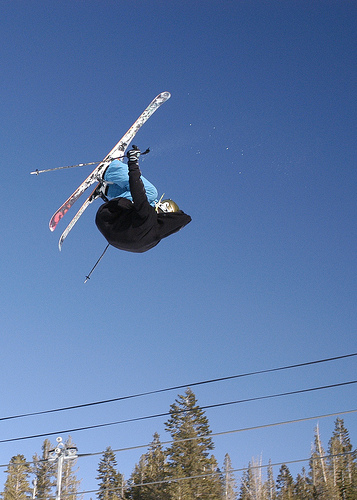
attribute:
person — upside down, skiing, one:
[89, 140, 195, 256]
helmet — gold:
[156, 194, 183, 227]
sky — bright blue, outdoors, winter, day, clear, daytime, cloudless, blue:
[2, 2, 356, 499]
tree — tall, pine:
[139, 386, 220, 500]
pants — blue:
[101, 155, 160, 207]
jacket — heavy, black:
[94, 158, 193, 255]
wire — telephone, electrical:
[1, 352, 356, 425]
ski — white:
[45, 88, 174, 237]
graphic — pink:
[49, 190, 75, 230]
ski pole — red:
[28, 145, 153, 179]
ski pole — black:
[82, 238, 110, 286]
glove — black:
[123, 142, 144, 170]